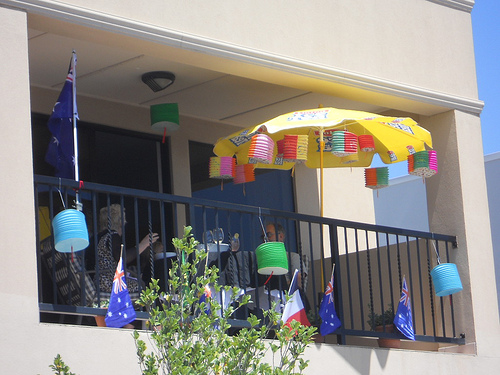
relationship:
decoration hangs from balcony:
[51, 208, 89, 261] [4, 0, 499, 375]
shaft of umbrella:
[316, 126, 326, 294] [213, 104, 434, 173]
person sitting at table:
[257, 223, 309, 288] [150, 240, 230, 290]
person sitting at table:
[86, 203, 160, 290] [150, 240, 230, 290]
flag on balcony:
[42, 47, 79, 204] [23, 20, 471, 341]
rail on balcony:
[35, 174, 463, 348] [31, 12, 476, 318]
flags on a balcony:
[391, 274, 415, 341] [2, 105, 472, 375]